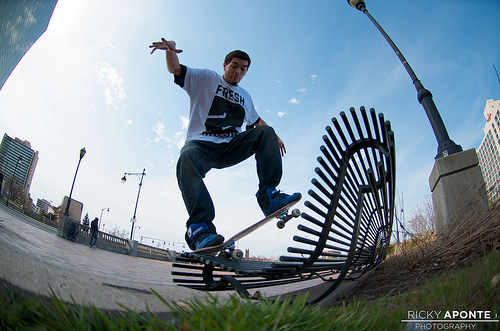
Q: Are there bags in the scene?
A: No, there are no bags.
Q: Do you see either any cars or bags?
A: No, there are no bags or cars.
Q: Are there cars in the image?
A: No, there are no cars.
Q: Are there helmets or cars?
A: No, there are no cars or helmets.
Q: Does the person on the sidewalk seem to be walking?
A: Yes, the person is walking.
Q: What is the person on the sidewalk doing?
A: The person is walking.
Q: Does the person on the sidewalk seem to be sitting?
A: No, the person is walking.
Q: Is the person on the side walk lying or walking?
A: The person is walking.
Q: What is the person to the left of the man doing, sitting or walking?
A: The person is walking.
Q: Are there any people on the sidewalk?
A: Yes, there is a person on the sidewalk.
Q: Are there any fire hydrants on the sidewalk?
A: No, there is a person on the sidewalk.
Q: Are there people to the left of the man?
A: Yes, there is a person to the left of the man.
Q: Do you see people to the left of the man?
A: Yes, there is a person to the left of the man.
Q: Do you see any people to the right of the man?
A: No, the person is to the left of the man.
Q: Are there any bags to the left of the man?
A: No, there is a person to the left of the man.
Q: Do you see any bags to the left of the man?
A: No, there is a person to the left of the man.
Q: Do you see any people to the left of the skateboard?
A: Yes, there is a person to the left of the skateboard.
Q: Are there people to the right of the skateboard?
A: No, the person is to the left of the skateboard.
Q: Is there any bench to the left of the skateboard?
A: No, there is a person to the left of the skateboard.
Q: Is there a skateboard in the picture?
A: Yes, there is a skateboard.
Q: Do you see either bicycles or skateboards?
A: Yes, there is a skateboard.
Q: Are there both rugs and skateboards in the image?
A: No, there is a skateboard but no rugs.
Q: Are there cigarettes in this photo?
A: No, there are no cigarettes.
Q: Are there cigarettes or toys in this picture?
A: No, there are no cigarettes or toys.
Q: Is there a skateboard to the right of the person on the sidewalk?
A: Yes, there is a skateboard to the right of the person.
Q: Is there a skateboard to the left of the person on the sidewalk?
A: No, the skateboard is to the right of the person.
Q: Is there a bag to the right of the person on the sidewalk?
A: No, there is a skateboard to the right of the person.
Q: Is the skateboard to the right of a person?
A: Yes, the skateboard is to the right of a person.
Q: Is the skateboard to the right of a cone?
A: No, the skateboard is to the right of a person.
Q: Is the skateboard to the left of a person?
A: No, the skateboard is to the right of a person.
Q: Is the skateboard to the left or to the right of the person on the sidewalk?
A: The skateboard is to the right of the person.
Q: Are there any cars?
A: No, there are no cars.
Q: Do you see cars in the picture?
A: No, there are no cars.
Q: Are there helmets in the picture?
A: No, there are no helmets.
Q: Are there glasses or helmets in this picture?
A: No, there are no helmets or glasses.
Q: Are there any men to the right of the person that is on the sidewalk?
A: Yes, there is a man to the right of the person.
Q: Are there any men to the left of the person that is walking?
A: No, the man is to the right of the person.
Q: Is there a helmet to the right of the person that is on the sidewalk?
A: No, there is a man to the right of the person.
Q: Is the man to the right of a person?
A: Yes, the man is to the right of a person.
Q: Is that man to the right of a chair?
A: No, the man is to the right of a person.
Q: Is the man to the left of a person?
A: No, the man is to the right of a person.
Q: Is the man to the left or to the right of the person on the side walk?
A: The man is to the right of the person.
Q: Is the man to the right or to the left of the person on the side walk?
A: The man is to the right of the person.